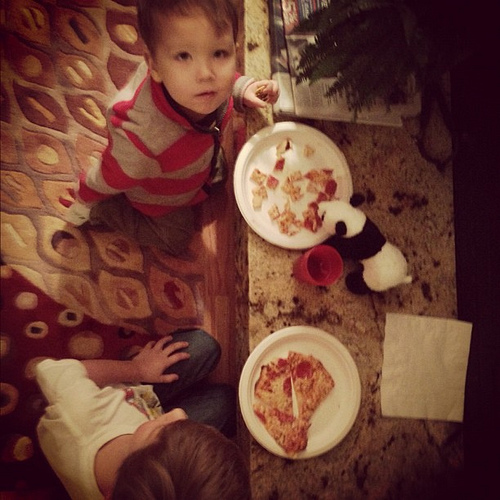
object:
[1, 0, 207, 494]
carpet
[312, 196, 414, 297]
panda plushie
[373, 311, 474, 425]
napkin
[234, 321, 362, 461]
plate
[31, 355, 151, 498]
sleeve shirt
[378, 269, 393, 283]
plushie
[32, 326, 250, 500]
boy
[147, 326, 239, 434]
jeans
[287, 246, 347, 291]
cup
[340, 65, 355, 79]
plant leaves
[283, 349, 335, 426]
pizza slice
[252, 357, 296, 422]
pizza slice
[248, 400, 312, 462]
pizza slice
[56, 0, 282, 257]
boy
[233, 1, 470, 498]
table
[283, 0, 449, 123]
plant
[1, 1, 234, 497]
floor